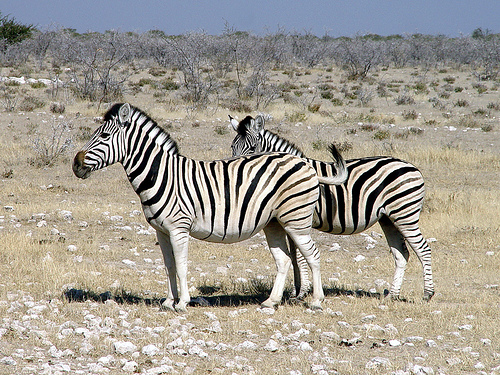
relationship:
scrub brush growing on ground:
[308, 100, 322, 113] [3, 24, 496, 374]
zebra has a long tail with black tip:
[65, 101, 351, 315] [316, 142, 349, 188]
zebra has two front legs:
[65, 101, 351, 315] [154, 233, 191, 313]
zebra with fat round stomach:
[65, 101, 351, 315] [194, 191, 277, 241]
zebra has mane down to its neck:
[65, 101, 351, 315] [122, 94, 184, 200]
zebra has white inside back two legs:
[65, 101, 351, 315] [259, 218, 294, 311]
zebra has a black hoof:
[226, 113, 440, 302] [422, 286, 434, 307]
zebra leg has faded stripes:
[65, 101, 351, 315] [166, 221, 192, 279]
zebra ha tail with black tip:
[65, 101, 351, 315] [316, 142, 349, 188]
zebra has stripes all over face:
[65, 101, 351, 315] [74, 107, 125, 181]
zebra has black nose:
[65, 101, 351, 315] [72, 152, 91, 181]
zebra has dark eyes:
[65, 101, 351, 315] [96, 129, 111, 143]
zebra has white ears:
[65, 101, 351, 315] [118, 102, 134, 125]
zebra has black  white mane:
[65, 101, 351, 315] [103, 102, 177, 159]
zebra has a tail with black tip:
[65, 101, 351, 315] [316, 142, 349, 188]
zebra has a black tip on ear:
[226, 113, 440, 302] [226, 114, 235, 121]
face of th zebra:
[74, 107, 125, 181] [65, 101, 351, 315]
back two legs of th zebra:
[259, 218, 294, 311] [65, 101, 351, 315]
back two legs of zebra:
[263, 223, 326, 318] [65, 101, 351, 315]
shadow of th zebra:
[62, 286, 289, 307] [65, 101, 351, 315]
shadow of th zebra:
[254, 282, 413, 307] [226, 113, 440, 302]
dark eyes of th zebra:
[98, 132, 112, 139] [65, 101, 351, 315]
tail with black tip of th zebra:
[316, 142, 349, 188] [65, 101, 351, 315]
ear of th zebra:
[226, 114, 235, 121] [226, 113, 440, 302]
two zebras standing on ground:
[73, 103, 436, 312] [3, 24, 496, 374]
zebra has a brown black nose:
[65, 101, 351, 315] [71, 152, 84, 172]